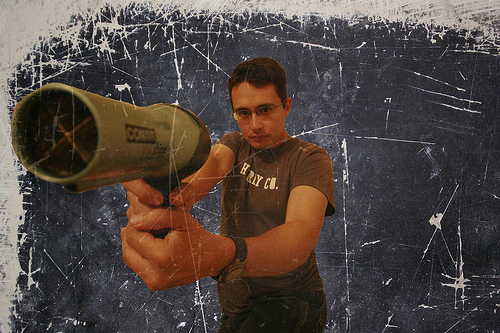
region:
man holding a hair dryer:
[37, 40, 361, 311]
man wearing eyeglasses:
[227, 88, 284, 139]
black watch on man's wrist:
[204, 223, 256, 299]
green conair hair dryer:
[29, 83, 211, 199]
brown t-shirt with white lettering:
[205, 111, 342, 306]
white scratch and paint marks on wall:
[390, 64, 490, 301]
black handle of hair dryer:
[129, 99, 219, 272]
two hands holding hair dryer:
[132, 162, 194, 290]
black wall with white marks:
[356, 76, 473, 281]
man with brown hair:
[210, 45, 302, 167]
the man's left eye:
[241, 103, 256, 121]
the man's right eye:
[262, 102, 273, 114]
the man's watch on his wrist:
[216, 234, 254, 281]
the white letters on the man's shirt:
[241, 160, 290, 194]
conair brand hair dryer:
[126, 120, 174, 153]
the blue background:
[351, 146, 418, 206]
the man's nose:
[253, 117, 263, 128]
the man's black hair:
[234, 47, 281, 81]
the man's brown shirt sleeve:
[293, 162, 339, 188]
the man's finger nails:
[126, 212, 148, 226]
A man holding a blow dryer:
[8, 25, 375, 328]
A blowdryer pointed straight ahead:
[10, 57, 220, 239]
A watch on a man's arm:
[207, 219, 262, 298]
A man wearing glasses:
[205, 44, 313, 155]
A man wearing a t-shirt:
[201, 53, 351, 315]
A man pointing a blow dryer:
[17, 17, 362, 298]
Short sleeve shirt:
[201, 126, 338, 256]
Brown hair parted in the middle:
[221, 45, 294, 120]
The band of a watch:
[220, 224, 253, 263]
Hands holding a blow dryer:
[115, 156, 207, 293]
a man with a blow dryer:
[6, 2, 394, 329]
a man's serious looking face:
[215, 45, 300, 161]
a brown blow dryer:
[5, 56, 217, 208]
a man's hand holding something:
[106, 205, 236, 301]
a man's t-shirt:
[195, 111, 361, 292]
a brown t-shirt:
[193, 115, 343, 292]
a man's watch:
[200, 216, 255, 308]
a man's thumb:
[120, 195, 201, 240]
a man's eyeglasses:
[227, 96, 278, 121]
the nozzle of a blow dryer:
[4, 78, 107, 198]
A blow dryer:
[6, 74, 214, 226]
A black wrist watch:
[218, 232, 255, 294]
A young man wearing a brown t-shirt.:
[233, 95, 287, 125]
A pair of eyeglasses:
[231, 101, 294, 123]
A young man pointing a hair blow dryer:
[8, 28, 367, 321]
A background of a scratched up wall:
[333, 4, 492, 331]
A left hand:
[113, 205, 213, 297]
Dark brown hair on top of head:
[224, 50, 301, 106]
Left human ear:
[281, 90, 299, 125]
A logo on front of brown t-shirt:
[238, 160, 286, 194]